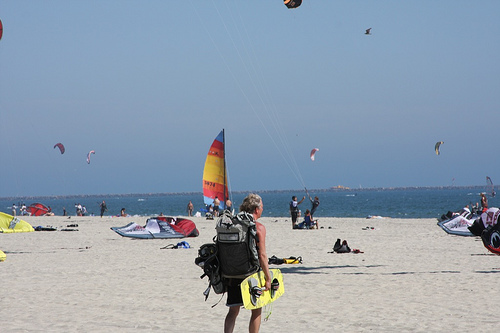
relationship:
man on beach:
[223, 193, 272, 333] [4, 214, 499, 332]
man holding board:
[223, 193, 272, 333] [239, 267, 285, 310]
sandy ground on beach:
[2, 217, 497, 330] [4, 214, 499, 332]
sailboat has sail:
[199, 127, 233, 217] [199, 126, 233, 215]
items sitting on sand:
[331, 237, 362, 254] [0, 214, 497, 328]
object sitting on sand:
[162, 239, 191, 249] [0, 214, 497, 328]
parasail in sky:
[308, 143, 324, 164] [0, 0, 500, 112]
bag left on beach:
[272, 252, 303, 268] [4, 214, 499, 332]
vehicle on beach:
[109, 213, 197, 246] [4, 214, 499, 332]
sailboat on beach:
[205, 206, 229, 221] [4, 214, 499, 332]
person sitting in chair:
[304, 209, 319, 230] [305, 216, 317, 230]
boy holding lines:
[303, 190, 320, 217] [170, 0, 308, 199]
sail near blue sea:
[202, 130, 229, 210] [0, 185, 500, 219]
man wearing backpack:
[222, 187, 276, 331] [212, 213, 259, 280]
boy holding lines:
[309, 196, 321, 220] [224, 0, 305, 188]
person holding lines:
[286, 190, 303, 228] [224, 0, 305, 188]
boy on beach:
[309, 196, 321, 220] [4, 214, 499, 332]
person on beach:
[286, 190, 303, 228] [4, 214, 499, 332]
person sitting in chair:
[306, 208, 316, 224] [303, 217, 315, 229]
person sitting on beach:
[306, 208, 316, 224] [4, 214, 499, 332]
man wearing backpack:
[222, 187, 276, 331] [210, 205, 255, 242]